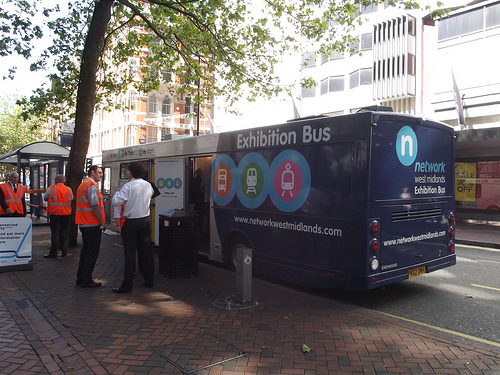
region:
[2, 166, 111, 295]
Men in orange safety vests.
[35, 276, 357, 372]
Cobblestone sidewalk with shadows.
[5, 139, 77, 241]
Bus stop.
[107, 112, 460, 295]
Blue "Exhibition Bus" with logos on side.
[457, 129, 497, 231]
Sale sign in store window.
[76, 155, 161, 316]
Men talking, on sidewalk.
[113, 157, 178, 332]
Tall man, standing on sidewalk, wearing white shirt and dark pants.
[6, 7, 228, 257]
Tall, leaning tree, near busstop.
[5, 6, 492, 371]
City street and sidewalk.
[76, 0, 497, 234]
Buildings along city street.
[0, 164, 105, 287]
Three men in orange vests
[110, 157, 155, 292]
A man in a white shirt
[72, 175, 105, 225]
A bright orange vest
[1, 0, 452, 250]
A tall tree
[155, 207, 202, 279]
Tall black outside trashcan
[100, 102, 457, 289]
A blue and white bus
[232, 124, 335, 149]
The words Exhibition Bus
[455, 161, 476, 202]
Yellow sign in a store window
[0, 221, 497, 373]
Sidewalk that is made of bricks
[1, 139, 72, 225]
White and black sheltered bus stop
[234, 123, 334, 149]
Says Exhibition bus on side of the bus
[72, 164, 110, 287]
man in bright orange safety vest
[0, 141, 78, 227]
glass bus stop with seating inside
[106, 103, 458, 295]
Big bus that is white and blue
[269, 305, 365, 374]
bricks making up a sidewalk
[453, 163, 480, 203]
yellow sign in window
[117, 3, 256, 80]
Branches of a tree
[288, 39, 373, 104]
windows on the front of a building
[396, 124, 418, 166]
blue circle with the letter n inside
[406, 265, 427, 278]
orange license plate on bus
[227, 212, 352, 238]
website address on the bus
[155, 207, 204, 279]
a black trash can by bus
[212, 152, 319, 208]
three different logos on the bus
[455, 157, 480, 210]
a yellow window advertisement with 75% off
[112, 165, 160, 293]
a man standing with white shirt and black pants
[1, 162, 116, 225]
three men wearing bright orange vests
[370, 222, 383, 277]
three lights on back of bus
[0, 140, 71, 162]
the top of a bus stand for passengers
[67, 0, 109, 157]
part of the trunk of a large tree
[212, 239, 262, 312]
a gray receptacle for cigarette butts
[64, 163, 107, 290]
A city worker wearing reflective material.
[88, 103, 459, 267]
A bus for transporting people.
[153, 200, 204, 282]
A trash can for litter removal.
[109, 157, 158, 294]
A bus driver waiting for passengers to board.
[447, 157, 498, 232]
A retail shop with advertising.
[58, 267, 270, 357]
A patterned brick walkway.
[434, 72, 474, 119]
A flag hanging above a storefront.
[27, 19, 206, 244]
A large tree.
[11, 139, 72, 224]
A bus stop terminal.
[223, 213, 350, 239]
A website displayed for advertising.